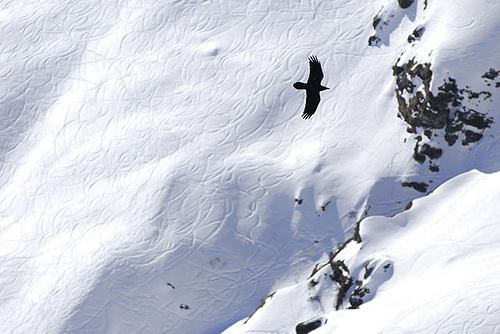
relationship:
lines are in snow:
[203, 101, 269, 155] [204, 101, 279, 190]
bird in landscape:
[296, 51, 332, 117] [0, 0, 500, 333]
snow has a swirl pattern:
[0, 0, 500, 334] [115, 146, 140, 173]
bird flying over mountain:
[294, 54, 332, 120] [6, 4, 485, 330]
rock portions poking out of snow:
[391, 54, 467, 160] [420, 23, 480, 68]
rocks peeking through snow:
[329, 259, 358, 307] [296, 250, 455, 332]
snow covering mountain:
[41, 44, 226, 230] [0, 0, 500, 330]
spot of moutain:
[413, 86, 466, 136] [0, 1, 495, 331]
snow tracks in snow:
[190, 70, 295, 216] [0, 0, 498, 331]